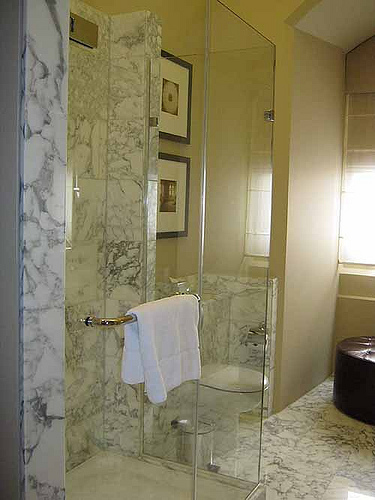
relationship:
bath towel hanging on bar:
[120, 292, 204, 399] [80, 291, 200, 326]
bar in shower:
[79, 291, 214, 328] [30, 1, 287, 497]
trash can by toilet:
[173, 417, 220, 471] [182, 362, 266, 472]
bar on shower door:
[80, 291, 200, 326] [73, 12, 199, 431]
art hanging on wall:
[156, 49, 192, 240] [141, 36, 239, 293]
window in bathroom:
[133, 211, 254, 427] [4, 2, 370, 498]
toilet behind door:
[192, 357, 268, 466] [149, 0, 276, 484]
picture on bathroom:
[145, 145, 194, 244] [0, 2, 375, 499]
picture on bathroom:
[154, 51, 196, 146] [0, 2, 375, 499]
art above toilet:
[128, 48, 204, 250] [181, 358, 271, 460]